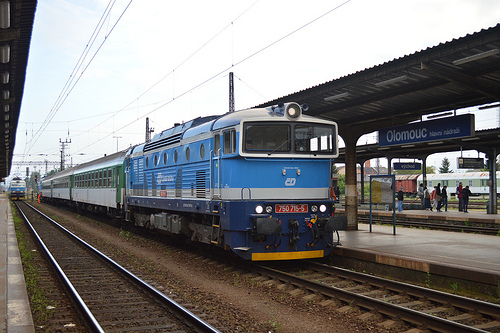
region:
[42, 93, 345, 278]
a train in a station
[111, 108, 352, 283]
its first compartment is blue in colour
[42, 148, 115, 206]
the compartments are white with green doors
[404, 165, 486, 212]
people standing at the station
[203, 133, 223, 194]
the door is closed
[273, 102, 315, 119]
it has a light and a horn on the front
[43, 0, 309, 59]
cables are crossing overhead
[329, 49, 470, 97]
the lights are switched off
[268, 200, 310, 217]
it has a red numberplate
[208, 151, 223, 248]
it is fitted with a ladder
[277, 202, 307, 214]
red and white sign on front of train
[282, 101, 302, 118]
light on the front of the train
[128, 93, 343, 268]
blue engine of the train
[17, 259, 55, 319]
grass near the train tracks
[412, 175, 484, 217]
people waiting at the train station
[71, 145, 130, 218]
green car of the train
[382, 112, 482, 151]
blue and white sign at the train station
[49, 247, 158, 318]
metal train tracks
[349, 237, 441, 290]
platform near the blue train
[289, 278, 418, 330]
train tracks in front of the blue train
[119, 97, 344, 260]
blue and white first train car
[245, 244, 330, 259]
yellow bumper on train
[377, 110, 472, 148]
white lettering on blue sign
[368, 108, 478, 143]
blue sign hanging from roof over platform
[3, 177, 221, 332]
train in background coming down tracks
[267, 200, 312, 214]
red background with white lettering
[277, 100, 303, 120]
light on top of train car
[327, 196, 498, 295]
train platform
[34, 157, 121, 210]
green and white cars of train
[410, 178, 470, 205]
people waiting on train platform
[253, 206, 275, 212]
The left headlight on the train.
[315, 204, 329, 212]
The right headlight on the train.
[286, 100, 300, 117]
The top headlight above the front windows of the train.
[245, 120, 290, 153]
The left front window of the train.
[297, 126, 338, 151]
The right front window of the train.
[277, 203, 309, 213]
The red license plate on the front of the train.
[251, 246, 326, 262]
The yellow stripe on the front of the train.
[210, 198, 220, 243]
The three yellow stairs on the side of the train near the front.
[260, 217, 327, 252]
The wires on the front of the train.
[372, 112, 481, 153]
The blue sign to the right of the train that reads Olomouc.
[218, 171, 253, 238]
edge of a train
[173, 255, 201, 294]
part of a ground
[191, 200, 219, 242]
part of a wheel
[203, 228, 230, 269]
part of a train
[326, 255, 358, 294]
dge of a rail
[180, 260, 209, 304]
part of a ground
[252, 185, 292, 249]
part of a train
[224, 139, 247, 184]
edge of a train